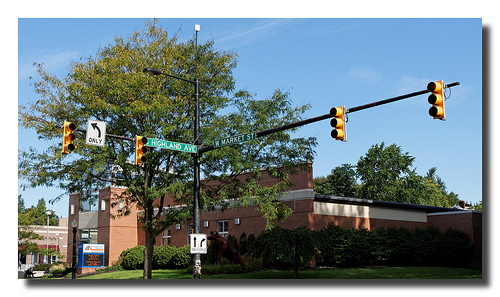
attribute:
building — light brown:
[64, 165, 498, 263]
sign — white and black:
[187, 230, 211, 256]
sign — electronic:
[77, 242, 107, 269]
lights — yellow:
[56, 113, 81, 165]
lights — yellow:
[118, 124, 154, 170]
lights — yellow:
[323, 93, 350, 153]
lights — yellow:
[416, 65, 453, 141]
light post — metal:
[125, 20, 231, 287]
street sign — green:
[135, 129, 260, 181]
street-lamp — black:
[70, 220, 77, 278]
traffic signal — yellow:
[328, 105, 346, 138]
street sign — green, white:
[142, 138, 198, 156]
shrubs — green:
[117, 221, 479, 270]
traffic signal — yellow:
[323, 98, 354, 145]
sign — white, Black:
[83, 111, 94, 143]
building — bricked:
[101, 154, 476, 250]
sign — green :
[207, 131, 259, 148]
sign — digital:
[72, 232, 116, 273]